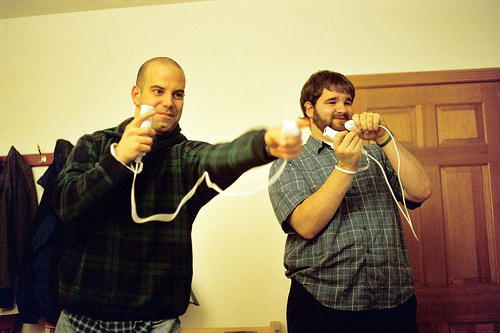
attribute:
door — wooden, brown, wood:
[344, 68, 496, 329]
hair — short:
[136, 56, 186, 95]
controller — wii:
[281, 119, 302, 138]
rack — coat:
[0, 143, 75, 172]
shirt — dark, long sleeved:
[61, 116, 279, 324]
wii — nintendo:
[131, 106, 301, 225]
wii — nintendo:
[325, 123, 419, 241]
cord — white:
[361, 124, 420, 240]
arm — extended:
[189, 124, 271, 193]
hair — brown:
[309, 107, 345, 133]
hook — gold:
[35, 143, 46, 164]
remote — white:
[321, 124, 366, 155]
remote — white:
[131, 103, 156, 163]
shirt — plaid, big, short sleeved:
[268, 126, 417, 316]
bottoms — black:
[285, 279, 421, 331]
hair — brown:
[298, 71, 356, 121]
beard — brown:
[311, 103, 345, 134]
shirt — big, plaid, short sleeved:
[269, 136, 421, 307]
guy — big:
[263, 68, 430, 330]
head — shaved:
[135, 53, 188, 88]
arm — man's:
[373, 131, 435, 203]